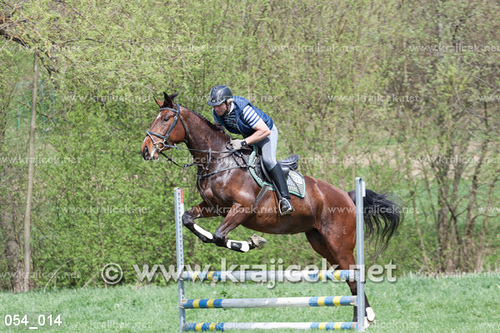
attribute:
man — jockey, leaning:
[207, 84, 295, 215]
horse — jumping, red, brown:
[141, 90, 403, 327]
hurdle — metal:
[174, 267, 365, 329]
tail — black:
[350, 186, 405, 260]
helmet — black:
[205, 83, 234, 106]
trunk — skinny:
[23, 49, 39, 293]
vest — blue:
[215, 96, 273, 137]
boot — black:
[269, 160, 295, 215]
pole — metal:
[352, 176, 367, 332]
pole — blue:
[175, 271, 362, 283]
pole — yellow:
[182, 292, 359, 308]